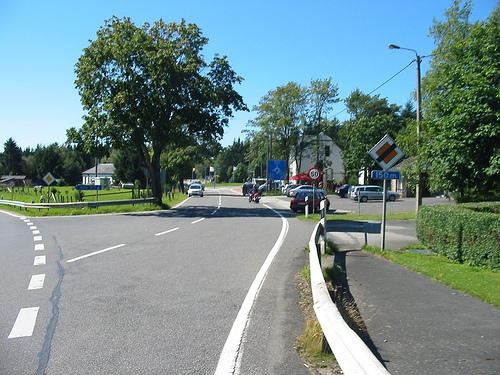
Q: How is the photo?
A: Clear.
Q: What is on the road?
A: White lines.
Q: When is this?
A: Daytime.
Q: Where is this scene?
A: On the street.